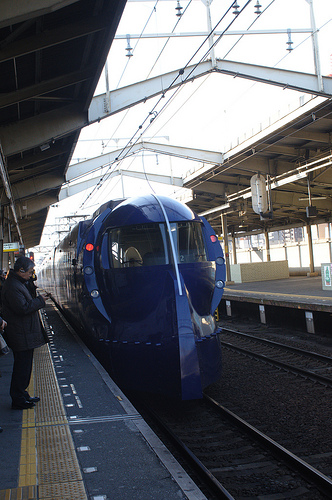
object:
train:
[32, 193, 227, 404]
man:
[0, 255, 48, 413]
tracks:
[154, 403, 234, 499]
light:
[85, 242, 94, 251]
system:
[32, 222, 79, 326]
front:
[231, 465, 332, 499]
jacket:
[0, 267, 49, 350]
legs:
[9, 351, 36, 409]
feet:
[11, 399, 34, 410]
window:
[108, 221, 207, 269]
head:
[14, 255, 36, 279]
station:
[0, 0, 332, 495]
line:
[18, 352, 37, 484]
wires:
[115, 0, 159, 89]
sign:
[250, 173, 268, 215]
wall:
[222, 236, 332, 274]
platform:
[0, 275, 212, 500]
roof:
[0, 0, 121, 253]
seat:
[123, 246, 142, 268]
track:
[206, 394, 332, 486]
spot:
[77, 444, 92, 452]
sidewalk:
[0, 292, 208, 500]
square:
[77, 444, 92, 453]